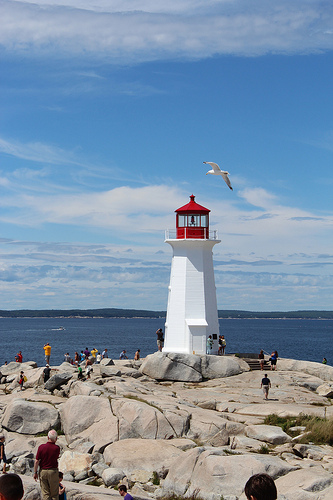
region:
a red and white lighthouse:
[157, 192, 227, 355]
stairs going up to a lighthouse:
[231, 351, 277, 372]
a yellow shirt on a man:
[43, 343, 52, 355]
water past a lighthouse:
[0, 317, 331, 367]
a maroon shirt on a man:
[35, 441, 62, 469]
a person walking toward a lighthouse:
[258, 368, 275, 401]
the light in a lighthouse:
[188, 214, 195, 225]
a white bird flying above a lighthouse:
[202, 157, 236, 192]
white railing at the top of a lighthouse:
[160, 225, 224, 242]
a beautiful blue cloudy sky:
[0, 0, 332, 310]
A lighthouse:
[153, 191, 229, 371]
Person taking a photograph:
[37, 340, 58, 368]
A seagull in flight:
[197, 151, 251, 196]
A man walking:
[256, 368, 280, 403]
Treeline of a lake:
[1, 301, 164, 325]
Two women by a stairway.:
[241, 344, 300, 372]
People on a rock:
[13, 368, 33, 398]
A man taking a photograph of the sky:
[140, 289, 164, 350]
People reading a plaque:
[205, 328, 228, 357]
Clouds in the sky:
[4, 137, 154, 288]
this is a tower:
[164, 201, 217, 336]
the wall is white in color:
[168, 267, 208, 310]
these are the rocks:
[132, 390, 217, 454]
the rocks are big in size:
[115, 398, 202, 463]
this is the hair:
[251, 475, 271, 490]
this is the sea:
[94, 314, 123, 339]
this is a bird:
[198, 157, 235, 184]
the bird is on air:
[187, 156, 239, 186]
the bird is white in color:
[200, 156, 238, 189]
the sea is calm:
[282, 323, 317, 349]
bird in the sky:
[190, 148, 240, 202]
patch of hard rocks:
[92, 393, 156, 463]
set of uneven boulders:
[80, 390, 201, 447]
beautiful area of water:
[237, 324, 311, 348]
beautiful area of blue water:
[235, 324, 316, 350]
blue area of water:
[233, 322, 315, 349]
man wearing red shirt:
[29, 425, 70, 470]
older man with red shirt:
[24, 421, 75, 486]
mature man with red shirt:
[25, 419, 77, 491]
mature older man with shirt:
[26, 419, 78, 487]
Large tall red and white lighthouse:
[165, 192, 223, 353]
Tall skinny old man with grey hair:
[33, 428, 61, 497]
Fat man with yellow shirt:
[42, 342, 50, 366]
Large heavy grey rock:
[137, 348, 249, 381]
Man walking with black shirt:
[259, 374, 272, 400]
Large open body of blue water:
[0, 317, 331, 364]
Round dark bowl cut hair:
[243, 473, 279, 498]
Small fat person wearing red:
[15, 350, 24, 364]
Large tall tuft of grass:
[261, 411, 332, 442]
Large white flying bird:
[203, 160, 233, 190]